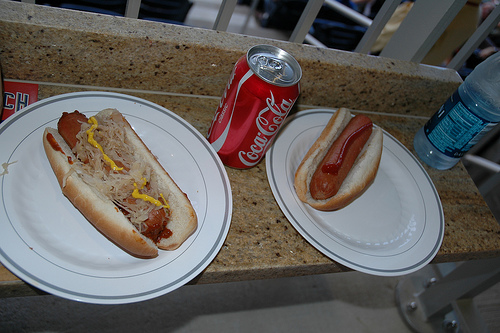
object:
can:
[205, 44, 301, 170]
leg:
[419, 257, 498, 320]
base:
[395, 276, 462, 333]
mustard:
[86, 116, 124, 173]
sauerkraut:
[62, 111, 170, 232]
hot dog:
[58, 110, 168, 238]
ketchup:
[321, 122, 373, 174]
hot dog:
[310, 114, 372, 200]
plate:
[0, 91, 233, 304]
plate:
[265, 107, 446, 277]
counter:
[0, 1, 499, 299]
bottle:
[412, 50, 500, 170]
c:
[3, 92, 15, 110]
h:
[15, 92, 29, 113]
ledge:
[1, 0, 466, 117]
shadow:
[114, 317, 194, 332]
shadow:
[338, 282, 426, 309]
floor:
[0, 258, 499, 332]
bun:
[43, 108, 198, 257]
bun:
[294, 107, 383, 211]